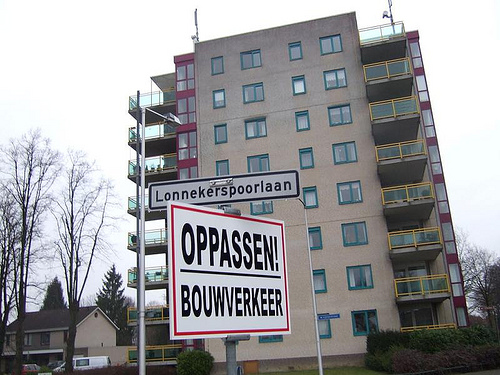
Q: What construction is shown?
A: Tall building.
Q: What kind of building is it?
A: Habitation building.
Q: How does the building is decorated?
A: Painted off white.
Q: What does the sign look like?
A: White rectangle.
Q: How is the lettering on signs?
A: Black letters.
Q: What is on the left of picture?
A: Trees.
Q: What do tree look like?
A: Tall with no leaves.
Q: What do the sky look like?
A: Gray but clear.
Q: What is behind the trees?
A: A house.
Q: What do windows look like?
A: Rectangular with blue sims.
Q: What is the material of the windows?
A: Glass.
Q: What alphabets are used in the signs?
A: English.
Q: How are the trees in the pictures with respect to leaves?
A: No leaves.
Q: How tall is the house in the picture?
A: 2 storeys.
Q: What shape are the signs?
A: Rectangle.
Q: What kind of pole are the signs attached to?
A: Silver pole.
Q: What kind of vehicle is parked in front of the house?
A: Truck.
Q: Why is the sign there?
A: To show information.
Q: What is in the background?
A: Buildings.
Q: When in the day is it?
A: Afternoon.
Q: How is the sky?
A: Overcast.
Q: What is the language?
A: German.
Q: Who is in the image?
A: No one.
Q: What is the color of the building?
A: Beige.